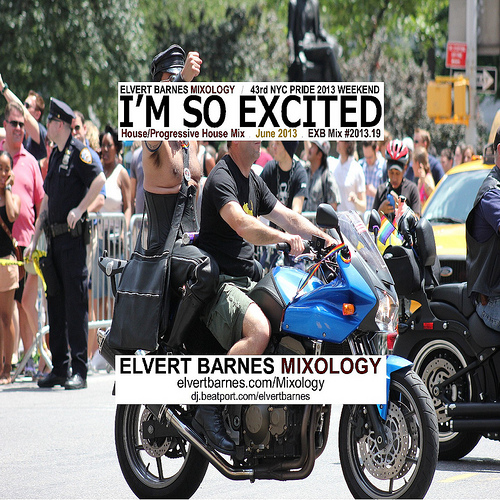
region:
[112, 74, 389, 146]
black and white so excited sign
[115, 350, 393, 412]
black and white elvert barnes sign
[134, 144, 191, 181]
hairy armpit of person on bike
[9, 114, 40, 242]
man in pink shirt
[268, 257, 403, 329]
blue portion of bike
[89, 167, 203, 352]
black messenger bag on person on bike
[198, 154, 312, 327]
man in green shorts driving bike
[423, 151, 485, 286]
yellow vehicle by crowd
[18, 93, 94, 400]
police officer by crowd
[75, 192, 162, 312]
silver metal fence by crowd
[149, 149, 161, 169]
long dark armpit hair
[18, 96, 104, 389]
police officer is standing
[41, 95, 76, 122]
police officer wearing a dark hat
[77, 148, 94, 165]
white patch on a dark shirt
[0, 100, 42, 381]
man wearing a pink polo shirt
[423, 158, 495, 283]
yellow taxi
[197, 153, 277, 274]
man wearing black t shirt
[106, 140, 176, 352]
large black cross body bag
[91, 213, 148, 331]
woman behind metal railing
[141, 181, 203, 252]
person wearing a black corset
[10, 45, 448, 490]
people riding a motorcycle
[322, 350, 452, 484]
the tire is black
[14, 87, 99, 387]
police officer in the background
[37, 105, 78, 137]
the officer is wearing sunglasses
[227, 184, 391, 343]
the bike is blue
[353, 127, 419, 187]
a man is wearing a helmet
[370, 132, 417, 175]
the helmet has red stripes on it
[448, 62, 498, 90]
the arrow is pointing right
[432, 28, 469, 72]
the sign is red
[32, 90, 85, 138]
the officer is wearing a hat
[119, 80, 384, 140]
event details posted on flyer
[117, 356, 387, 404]
website address posted on flyer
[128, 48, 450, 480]
two people riding on a motorcycle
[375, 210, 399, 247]
rainbow pride flag on the back of a bike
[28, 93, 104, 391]
a police officer standing guard for crowd patrol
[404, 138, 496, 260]
taxi cab in the middle of a crowd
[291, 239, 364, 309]
gay pride streamer tied to mirror of motorcycle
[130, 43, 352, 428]
two men riding on a motorcycle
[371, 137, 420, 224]
a person wearing a bicycle helmet checking an electronic device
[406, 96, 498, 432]
a man riding on a motorcycle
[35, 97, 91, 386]
officer standing near metal barrier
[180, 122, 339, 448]
man driving huge blue motorcycle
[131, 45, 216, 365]
shirtless man riding on motorcycle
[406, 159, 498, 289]
yellow vehicle parked near barrier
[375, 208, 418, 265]
rainbow colored flag attached to motorcycle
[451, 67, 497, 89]
one way sign attached to pole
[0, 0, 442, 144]
huge green trees behind crowd of people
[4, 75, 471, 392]
huge crowd of people behind barrier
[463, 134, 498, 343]
man wearing a black vest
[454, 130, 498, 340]
man wearing jeans driving motorcycle